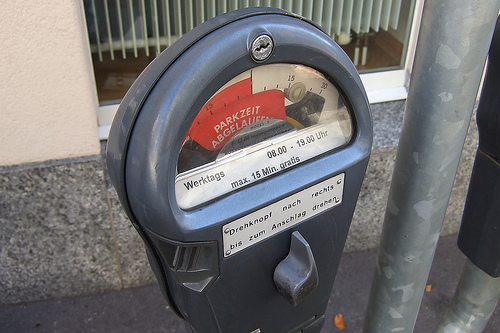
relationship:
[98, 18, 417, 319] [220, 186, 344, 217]
meter has letters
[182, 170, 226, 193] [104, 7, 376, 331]
word on meter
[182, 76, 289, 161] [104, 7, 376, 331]
label on meter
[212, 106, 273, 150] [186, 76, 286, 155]
lettering on label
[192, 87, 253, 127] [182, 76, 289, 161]
numbers on label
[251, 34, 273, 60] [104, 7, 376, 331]
keyhole on meter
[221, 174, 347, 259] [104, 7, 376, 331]
label on meter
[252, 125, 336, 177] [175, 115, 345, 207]
numbers on label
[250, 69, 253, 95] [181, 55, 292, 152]
line on label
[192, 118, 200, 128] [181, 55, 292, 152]
line on label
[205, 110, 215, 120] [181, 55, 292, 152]
line on label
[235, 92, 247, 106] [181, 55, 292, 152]
line on label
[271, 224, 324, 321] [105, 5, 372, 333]
knob on meter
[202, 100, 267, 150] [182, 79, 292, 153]
lettering on background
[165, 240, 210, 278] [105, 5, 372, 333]
coin slot on meter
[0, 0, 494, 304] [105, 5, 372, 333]
building behind meter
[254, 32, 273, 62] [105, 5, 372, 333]
keyhole on meter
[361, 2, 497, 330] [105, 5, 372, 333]
pole beside meter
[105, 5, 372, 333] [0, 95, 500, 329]
meter on sidewalk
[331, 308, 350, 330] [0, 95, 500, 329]
leaf on sidewalk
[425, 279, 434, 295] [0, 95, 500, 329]
leaf on sidewalk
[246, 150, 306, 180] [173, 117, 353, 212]
numbers on background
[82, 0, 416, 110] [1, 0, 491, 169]
window on building